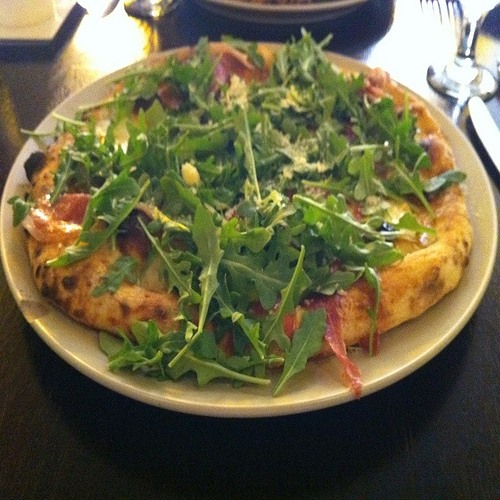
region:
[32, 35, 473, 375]
pizza on a plate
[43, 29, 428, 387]
greens on the pizza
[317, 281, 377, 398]
a slice of bacon on the pizza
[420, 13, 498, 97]
a spoon behind the plate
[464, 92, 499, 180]
a knife beside the plate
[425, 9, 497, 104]
the spoon is metal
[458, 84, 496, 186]
the knife is metal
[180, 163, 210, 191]
a grain of corn on the pizza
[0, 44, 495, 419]
the plate is beige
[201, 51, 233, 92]
a purple onion slice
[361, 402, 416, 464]
part of a shade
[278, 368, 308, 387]
part of a stalk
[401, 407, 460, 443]
edge of a shade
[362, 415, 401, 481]
part of a shade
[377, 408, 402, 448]
part of a shade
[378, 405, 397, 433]
part of a shade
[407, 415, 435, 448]
edge of a shade